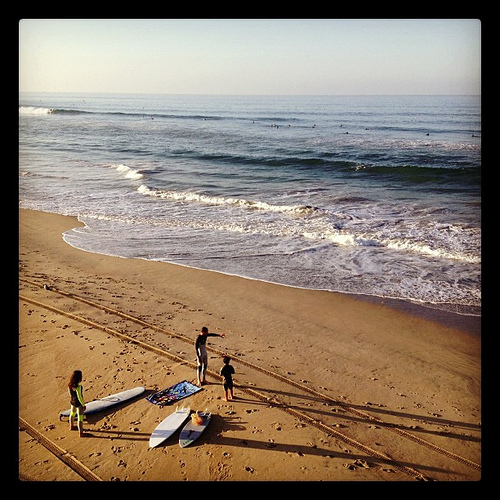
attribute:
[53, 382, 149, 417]
surfboard — longest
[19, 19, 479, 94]
sky — blue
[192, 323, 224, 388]
man — hand out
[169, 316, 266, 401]
persons — three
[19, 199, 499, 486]
shore — tide , coming 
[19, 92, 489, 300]
sea — Blue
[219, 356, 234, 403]
boy — little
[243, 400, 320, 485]
sand — wet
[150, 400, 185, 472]
surf board — white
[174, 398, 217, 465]
surf board — white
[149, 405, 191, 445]
surfboard — white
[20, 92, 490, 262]
water — large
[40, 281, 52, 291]
bird — lone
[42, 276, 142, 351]
lines — tire 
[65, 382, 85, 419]
wetsuit — yellow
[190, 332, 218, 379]
wetsuit — white, black